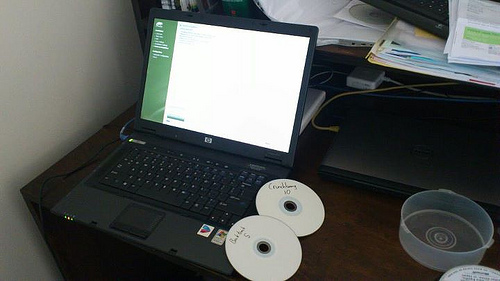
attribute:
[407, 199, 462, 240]
cd case — top, plastic, round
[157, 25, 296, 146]
screen — on, white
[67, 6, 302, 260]
laptop — black, closed, open, here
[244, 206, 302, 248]
discs — white, writing, 5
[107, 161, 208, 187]
keyboard — black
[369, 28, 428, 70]
papers — piled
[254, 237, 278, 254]
cds — hole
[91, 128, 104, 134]
table — brown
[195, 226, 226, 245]
stickers — logo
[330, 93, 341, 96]
wire — yellow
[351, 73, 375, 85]
box — white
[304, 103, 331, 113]
router — here